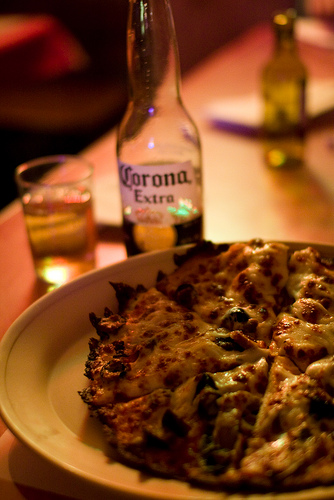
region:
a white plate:
[9, 237, 331, 496]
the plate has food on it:
[0, 240, 327, 493]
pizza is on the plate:
[80, 238, 326, 485]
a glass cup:
[14, 151, 106, 276]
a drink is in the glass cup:
[12, 160, 110, 284]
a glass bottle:
[104, 2, 230, 237]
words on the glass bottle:
[116, 160, 192, 204]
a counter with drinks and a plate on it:
[1, 2, 325, 484]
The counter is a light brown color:
[3, 4, 329, 491]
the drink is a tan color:
[16, 154, 102, 280]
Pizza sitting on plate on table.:
[1, 238, 328, 498]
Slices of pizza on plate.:
[72, 230, 332, 489]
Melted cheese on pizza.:
[146, 317, 213, 365]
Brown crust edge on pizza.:
[75, 301, 101, 410]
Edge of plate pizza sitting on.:
[0, 285, 73, 475]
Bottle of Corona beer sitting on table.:
[111, 3, 207, 250]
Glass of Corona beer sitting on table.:
[12, 151, 102, 286]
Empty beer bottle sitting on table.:
[246, 6, 319, 172]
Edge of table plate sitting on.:
[2, 197, 25, 309]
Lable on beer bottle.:
[113, 157, 198, 224]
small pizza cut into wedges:
[74, 233, 328, 494]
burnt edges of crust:
[87, 235, 219, 375]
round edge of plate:
[1, 242, 187, 494]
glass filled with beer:
[14, 149, 95, 281]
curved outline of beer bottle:
[113, 1, 200, 252]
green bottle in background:
[256, 5, 303, 165]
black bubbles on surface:
[148, 261, 261, 351]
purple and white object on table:
[205, 61, 326, 135]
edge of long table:
[3, 2, 269, 216]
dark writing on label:
[111, 157, 203, 206]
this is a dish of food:
[82, 234, 324, 442]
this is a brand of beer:
[36, 114, 237, 260]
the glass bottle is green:
[254, 14, 325, 194]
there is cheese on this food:
[124, 284, 297, 442]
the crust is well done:
[84, 278, 158, 433]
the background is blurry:
[31, 8, 315, 176]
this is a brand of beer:
[106, 149, 204, 211]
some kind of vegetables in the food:
[128, 366, 248, 446]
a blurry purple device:
[212, 72, 330, 149]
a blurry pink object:
[2, 9, 84, 92]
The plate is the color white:
[5, 305, 93, 481]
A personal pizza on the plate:
[83, 232, 330, 490]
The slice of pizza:
[82, 281, 262, 407]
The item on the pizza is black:
[218, 323, 244, 358]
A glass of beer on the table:
[14, 150, 107, 290]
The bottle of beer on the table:
[110, 0, 208, 260]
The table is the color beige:
[232, 168, 319, 226]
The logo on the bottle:
[112, 159, 199, 211]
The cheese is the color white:
[161, 326, 207, 361]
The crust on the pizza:
[77, 275, 131, 407]